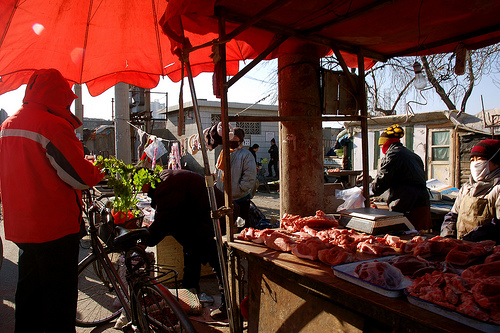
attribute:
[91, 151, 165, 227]
plants — potted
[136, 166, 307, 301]
man — in black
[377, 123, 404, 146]
marvin — yellow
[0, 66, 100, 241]
jacket — red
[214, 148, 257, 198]
jacket — silver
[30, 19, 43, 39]
bulb — single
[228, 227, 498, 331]
display counter — wooden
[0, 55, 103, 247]
jacket — orange, hooded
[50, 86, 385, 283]
food market — outdoor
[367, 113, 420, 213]
vendor — female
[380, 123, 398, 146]
hat — orange, green